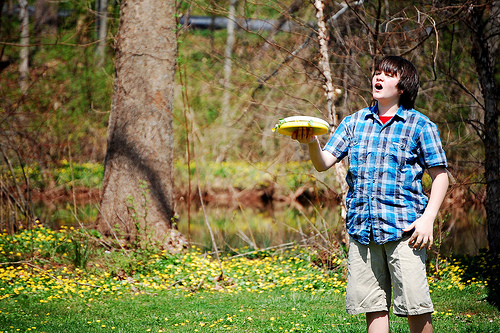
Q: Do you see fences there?
A: No, there are no fences.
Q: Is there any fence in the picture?
A: No, there are no fences.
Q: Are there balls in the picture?
A: No, there are no balls.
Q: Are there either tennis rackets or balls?
A: No, there are no balls or tennis rackets.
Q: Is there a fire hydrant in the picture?
A: No, there are no fire hydrants.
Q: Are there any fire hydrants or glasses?
A: No, there are no fire hydrants or glasses.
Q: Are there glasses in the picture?
A: No, there are no glasses.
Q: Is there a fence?
A: No, there are no fences.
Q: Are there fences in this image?
A: No, there are no fences.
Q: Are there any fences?
A: No, there are no fences.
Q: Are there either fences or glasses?
A: No, there are no fences or glasses.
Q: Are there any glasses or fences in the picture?
A: No, there are no fences or glasses.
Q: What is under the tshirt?
A: The shirt is under the tshirt.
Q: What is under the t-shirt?
A: The shirt is under the tshirt.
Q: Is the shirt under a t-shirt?
A: Yes, the shirt is under a t-shirt.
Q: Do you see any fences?
A: No, there are no fences.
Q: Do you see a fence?
A: No, there are no fences.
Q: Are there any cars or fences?
A: No, there are no fences or cars.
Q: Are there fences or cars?
A: No, there are no fences or cars.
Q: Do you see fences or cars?
A: No, there are no fences or cars.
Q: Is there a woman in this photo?
A: No, there are no women.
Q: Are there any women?
A: No, there are no women.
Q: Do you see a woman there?
A: No, there are no women.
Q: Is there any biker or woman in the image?
A: No, there are no women or bikers.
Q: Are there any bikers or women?
A: No, there are no women or bikers.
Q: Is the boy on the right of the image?
A: Yes, the boy is on the right of the image.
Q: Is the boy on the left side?
A: No, the boy is on the right of the image.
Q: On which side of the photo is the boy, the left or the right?
A: The boy is on the right of the image.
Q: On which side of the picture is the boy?
A: The boy is on the right of the image.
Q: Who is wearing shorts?
A: The boy is wearing shorts.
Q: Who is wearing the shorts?
A: The boy is wearing shorts.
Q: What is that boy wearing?
A: The boy is wearing shorts.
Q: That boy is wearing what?
A: The boy is wearing shorts.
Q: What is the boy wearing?
A: The boy is wearing shorts.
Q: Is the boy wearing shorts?
A: Yes, the boy is wearing shorts.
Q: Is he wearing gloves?
A: No, the boy is wearing shorts.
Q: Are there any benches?
A: No, there are no benches.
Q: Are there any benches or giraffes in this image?
A: No, there are no benches or giraffes.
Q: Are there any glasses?
A: No, there are no glasses.